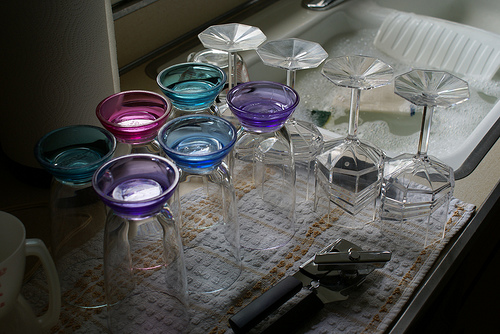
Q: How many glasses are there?
A: 8.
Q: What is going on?
A: Washing dishes.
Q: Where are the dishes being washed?
A: The sink.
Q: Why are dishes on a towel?
A: To dry.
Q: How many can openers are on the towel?
A: 1.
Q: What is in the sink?
A: Water.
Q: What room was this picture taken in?
A: The kitchen.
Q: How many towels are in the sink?
A: 1.